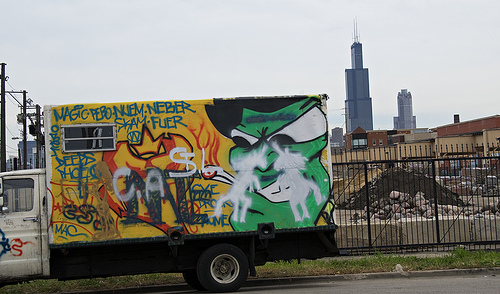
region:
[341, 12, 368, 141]
tall skyscraper building in the background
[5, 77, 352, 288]
truck parked on side of street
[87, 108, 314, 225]
truck painted with graffiti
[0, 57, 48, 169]
tall brown telephone and utility poles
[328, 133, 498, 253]
black metal fence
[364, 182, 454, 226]
pile of rocks on other side of fence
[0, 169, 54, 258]
white door of truck with red and blue graffiti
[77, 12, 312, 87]
light blue overcast sky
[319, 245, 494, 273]
small path of grass along street and sidewalk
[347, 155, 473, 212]
large pile of brown dirt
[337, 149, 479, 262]
black metal fence on the side of the road.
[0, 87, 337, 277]
white box truck with paint all over it.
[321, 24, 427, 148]
tall city buildings in the back ground.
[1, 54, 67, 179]
power poles and lines going down the street.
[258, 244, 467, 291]
broken concrete curb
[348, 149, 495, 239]
pile of dirt and rock behind the fence.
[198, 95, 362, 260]
large green face and lightning on the side of the box truck.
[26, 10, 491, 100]
gloomy skies about the city.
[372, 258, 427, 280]
trash on the side of the road.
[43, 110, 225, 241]
window and other graphite on the side of the truck.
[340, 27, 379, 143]
city building on horizon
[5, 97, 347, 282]
truck parked on street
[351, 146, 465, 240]
black metal fence on sidewalk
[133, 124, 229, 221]
graffiti on parked truck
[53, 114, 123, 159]
rectangle window on truck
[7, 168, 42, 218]
window on driver's side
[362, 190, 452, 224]
pile of rocks behind fence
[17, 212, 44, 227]
handle on parked truck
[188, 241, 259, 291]
back tire on truck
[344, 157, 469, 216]
pile of dirt behind fence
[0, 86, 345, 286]
a truck with graffiti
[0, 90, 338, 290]
a truck with colorful decoration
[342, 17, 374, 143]
a skyscraper in the distance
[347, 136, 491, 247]
an iron fence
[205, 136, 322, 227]
two unicorns dancing together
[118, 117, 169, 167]
a three pointed crown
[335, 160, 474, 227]
piles of debris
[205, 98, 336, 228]
a caricature of a green faced creature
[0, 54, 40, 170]
a row of telephone poles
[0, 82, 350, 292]
truck parked on downhill grade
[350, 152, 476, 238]
rail is black color.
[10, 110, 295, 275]
One truck is parked.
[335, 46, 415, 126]
Towers are seen behind the truck.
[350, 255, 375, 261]
Grass is green color.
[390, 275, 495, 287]
Road is grey color.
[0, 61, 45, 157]
poles are brown color.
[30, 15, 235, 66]
Sky is white color.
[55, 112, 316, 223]
Picture is drawn in the truck.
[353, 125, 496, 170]
building is brown color.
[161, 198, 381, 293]
Truck is parked in road.